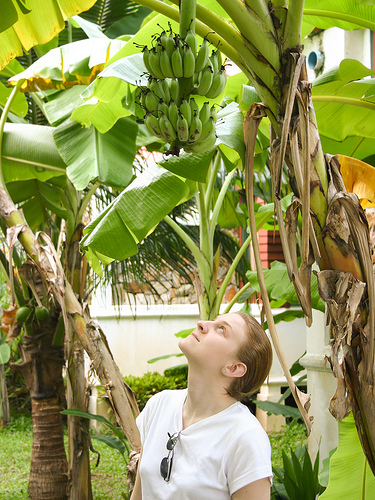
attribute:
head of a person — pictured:
[169, 304, 275, 416]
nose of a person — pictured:
[191, 318, 210, 335]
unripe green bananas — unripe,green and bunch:
[121, 13, 235, 154]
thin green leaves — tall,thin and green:
[2, 0, 248, 318]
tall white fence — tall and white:
[49, 296, 364, 453]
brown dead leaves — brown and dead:
[1, 58, 372, 425]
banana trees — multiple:
[2, 9, 367, 497]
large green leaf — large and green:
[16, 67, 149, 195]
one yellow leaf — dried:
[318, 143, 373, 214]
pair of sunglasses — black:
[157, 429, 187, 487]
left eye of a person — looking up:
[213, 322, 232, 336]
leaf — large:
[90, 158, 235, 260]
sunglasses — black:
[147, 449, 178, 481]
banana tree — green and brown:
[26, 318, 77, 444]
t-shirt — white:
[141, 406, 264, 489]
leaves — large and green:
[75, 168, 194, 265]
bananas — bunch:
[152, 74, 206, 142]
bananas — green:
[137, 121, 220, 204]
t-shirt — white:
[129, 386, 272, 497]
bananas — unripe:
[126, 22, 242, 157]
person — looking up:
[116, 312, 281, 498]